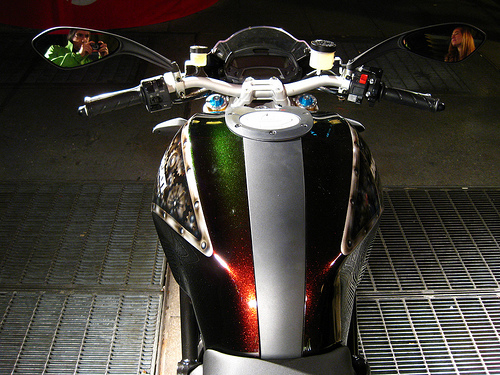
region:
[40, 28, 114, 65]
man in green jacket in rear view mirror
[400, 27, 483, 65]
long haired woman in rear view mirror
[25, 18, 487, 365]
front of motorcycle from behind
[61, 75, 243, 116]
left handlebar of motorcycle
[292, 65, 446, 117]
right handlebar of motorcycle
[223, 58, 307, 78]
odometer screen of motorcycle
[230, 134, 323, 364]
silver stripe on back of motorcycle gas tank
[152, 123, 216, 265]
intricate design on motorcycle tank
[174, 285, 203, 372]
shock on a motorcycle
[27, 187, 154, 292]
metal grill on floor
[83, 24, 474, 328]
This is a motorcylce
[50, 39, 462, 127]
These are handlebars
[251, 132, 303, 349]
This is a silver stripe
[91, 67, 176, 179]
The handle is rubber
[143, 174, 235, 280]
This is a decal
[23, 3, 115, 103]
This is a mirror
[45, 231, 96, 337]
This is a metal vent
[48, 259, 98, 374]
The vent is rusty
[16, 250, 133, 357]
The vent is dirty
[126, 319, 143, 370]
The vent is grey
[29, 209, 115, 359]
The drain cover is made of metal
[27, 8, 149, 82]
A man in the rear view mirror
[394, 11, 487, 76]
A woman in the rear view mirror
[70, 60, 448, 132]
The handle bars on the motorcycle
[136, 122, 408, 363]
The motorcycle is multi colored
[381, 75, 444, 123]
The rubber grip on the motorcycle is black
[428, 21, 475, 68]
The woman has brown hair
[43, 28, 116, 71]
The man is wearing a green jacket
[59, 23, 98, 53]
The man has black hair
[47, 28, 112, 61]
The man is holding a camera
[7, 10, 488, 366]
front half of a motorcycle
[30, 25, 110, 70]
reflection of man taking the photo in the mirror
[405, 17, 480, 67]
reflection of his possible wife in the mirror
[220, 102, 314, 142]
gas cap of motorcycle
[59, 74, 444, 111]
handle bars of motorcycle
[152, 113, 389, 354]
custom paint job of motorcycle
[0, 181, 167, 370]
set of grating on the floor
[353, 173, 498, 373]
set of grating on the floor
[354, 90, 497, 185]
concrete flooring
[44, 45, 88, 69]
mans green jacket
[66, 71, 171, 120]
one black left hand motorcycle handle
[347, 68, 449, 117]
one black right hand motorcycle handle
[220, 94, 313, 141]
one round metal motorcycle piece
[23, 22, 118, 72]
motorcycle mirror reflection of man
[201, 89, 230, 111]
one round shiny motorcycle part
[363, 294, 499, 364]
metal patterned floor grate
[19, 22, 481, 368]
one black motorcycle front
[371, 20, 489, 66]
right hand motorcycle mirror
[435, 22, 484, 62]
mirrored reflection of blonde woman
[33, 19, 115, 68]
mirrored reflection of man wearing green jacket